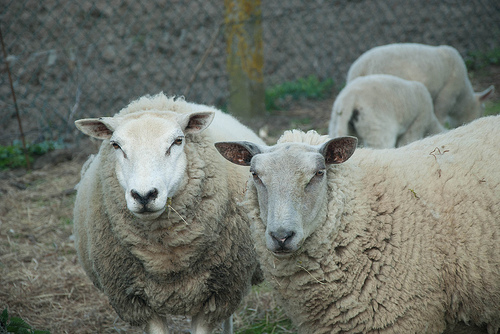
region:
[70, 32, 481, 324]
four sheep standing in a pen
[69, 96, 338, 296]
sheep have white whool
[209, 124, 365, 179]
sheep have ears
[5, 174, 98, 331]
hay on the ground of the pen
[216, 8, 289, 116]
post holding up the fence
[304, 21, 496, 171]
two sheep grazing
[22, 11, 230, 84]
chain link fence around the pen area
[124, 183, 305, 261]
sheep have dark noses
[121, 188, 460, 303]
sheep have rough beige whool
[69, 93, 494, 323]
sheep ready to be shorn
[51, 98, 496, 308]
two sheep standing close to each other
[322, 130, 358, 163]
the left ear of a sheep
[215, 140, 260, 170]
the right ear of a sheep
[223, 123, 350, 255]
the head of a sheep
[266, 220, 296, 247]
a sheep's nose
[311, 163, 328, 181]
the left eye of a sheep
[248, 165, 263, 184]
the right eye of a sheep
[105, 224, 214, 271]
the wool of a sheep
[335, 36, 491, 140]
two sheep that are feeding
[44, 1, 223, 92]
a chain link fence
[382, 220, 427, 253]
wool on the sheep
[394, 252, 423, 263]
wool on the sheep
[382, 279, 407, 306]
wool on the sheep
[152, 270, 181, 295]
wool on the sheep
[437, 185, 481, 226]
wool on the sheep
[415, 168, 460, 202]
wool on the sheep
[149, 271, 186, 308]
wool on the sheep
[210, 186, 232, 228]
wool on the sheep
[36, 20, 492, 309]
sheep in a pen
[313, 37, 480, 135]
these sheep have been sheared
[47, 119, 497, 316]
these sheep still have fur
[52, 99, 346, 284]
these sheep are adults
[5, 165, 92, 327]
the ground looks muddy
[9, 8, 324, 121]
a fence behind the sheep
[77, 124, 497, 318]
the sheep's fur is thick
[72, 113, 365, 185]
the sheeps ears stick out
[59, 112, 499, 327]
these sheep have an off white color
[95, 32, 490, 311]
there are four sheep in this shot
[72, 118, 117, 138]
The left ear of the sheep on the left.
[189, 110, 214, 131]
The right ear of the sheep on the left.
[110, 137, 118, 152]
The left eye of the sheep on the left.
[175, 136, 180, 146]
The right eye of the sheep on the left.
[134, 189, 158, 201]
The nose of the sheep on the left.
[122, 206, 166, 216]
The mouth of the sheep on the left.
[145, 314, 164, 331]
The front left leg of the sheep on the left.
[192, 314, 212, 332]
The front right leg of the sheep on the left.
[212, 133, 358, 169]
The ears of the sheep on the right.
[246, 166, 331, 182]
The eyes of the sheep on the right.